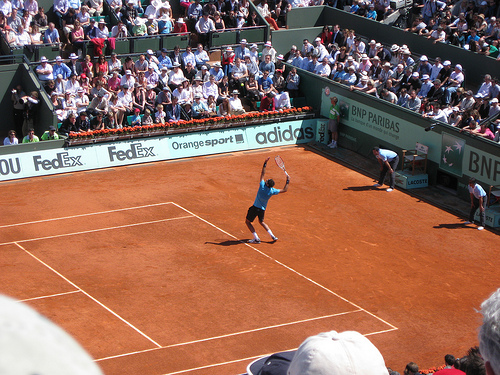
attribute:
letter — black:
[23, 145, 72, 174]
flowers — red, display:
[67, 107, 322, 142]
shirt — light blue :
[250, 189, 275, 208]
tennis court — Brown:
[7, 203, 468, 363]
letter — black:
[125, 142, 137, 161]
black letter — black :
[115, 148, 126, 160]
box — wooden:
[392, 165, 431, 190]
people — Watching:
[0, 0, 499, 143]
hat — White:
[246, 329, 401, 374]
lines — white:
[0, 202, 399, 358]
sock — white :
[246, 232, 263, 246]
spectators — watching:
[34, 54, 54, 81]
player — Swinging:
[231, 154, 336, 256]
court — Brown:
[51, 206, 285, 321]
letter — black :
[255, 130, 267, 145]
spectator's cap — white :
[246, 327, 388, 372]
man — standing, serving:
[237, 150, 296, 242]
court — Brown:
[333, 228, 410, 283]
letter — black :
[53, 148, 60, 172]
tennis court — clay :
[2, 197, 402, 372]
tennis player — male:
[243, 157, 289, 245]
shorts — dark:
[245, 203, 268, 224]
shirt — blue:
[251, 175, 280, 211]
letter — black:
[465, 147, 482, 178]